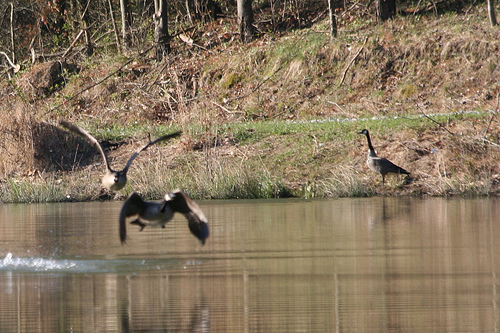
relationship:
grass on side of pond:
[88, 109, 498, 144] [6, 187, 499, 329]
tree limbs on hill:
[252, 32, 381, 112] [25, 12, 498, 228]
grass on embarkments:
[0, 1, 500, 205] [0, 195, 500, 333]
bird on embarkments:
[357, 129, 411, 186] [0, 195, 500, 333]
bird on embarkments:
[119, 187, 210, 248] [0, 195, 500, 333]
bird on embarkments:
[58, 118, 184, 193] [0, 195, 500, 333]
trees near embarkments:
[13, 1, 422, 46] [0, 195, 500, 333]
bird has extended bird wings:
[58, 118, 184, 193] [57, 116, 112, 173]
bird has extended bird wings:
[58, 118, 184, 193] [124, 131, 182, 174]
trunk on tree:
[229, 1, 275, 68] [42, 20, 496, 87]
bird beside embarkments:
[331, 121, 437, 196] [0, 195, 500, 333]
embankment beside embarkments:
[11, 44, 483, 179] [0, 195, 500, 333]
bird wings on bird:
[168, 187, 210, 247] [117, 187, 212, 250]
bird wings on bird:
[119, 192, 149, 247] [117, 187, 212, 250]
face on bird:
[354, 125, 370, 138] [357, 129, 411, 186]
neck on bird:
[365, 138, 375, 153] [357, 129, 411, 186]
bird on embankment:
[357, 129, 411, 186] [2, 107, 497, 202]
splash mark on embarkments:
[0, 245, 75, 270] [0, 195, 500, 333]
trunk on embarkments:
[236, 1, 260, 42] [10, 174, 499, 331]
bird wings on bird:
[114, 192, 145, 247] [100, 167, 232, 260]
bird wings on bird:
[168, 190, 216, 245] [100, 167, 232, 260]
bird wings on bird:
[123, 130, 183, 175] [100, 167, 232, 260]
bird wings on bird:
[61, 121, 113, 170] [100, 167, 232, 260]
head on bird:
[359, 127, 369, 137] [358, 127, 410, 184]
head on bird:
[100, 159, 129, 177] [51, 100, 202, 219]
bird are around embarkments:
[119, 187, 210, 248] [0, 195, 500, 333]